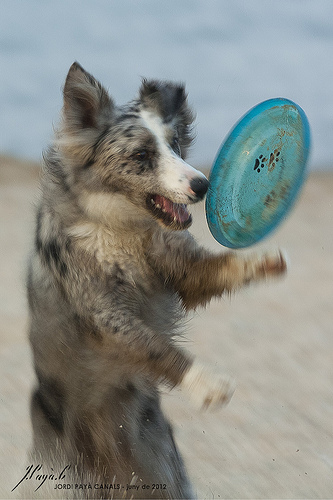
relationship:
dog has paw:
[26, 58, 290, 500] [201, 245, 297, 290]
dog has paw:
[26, 58, 290, 500] [179, 352, 238, 414]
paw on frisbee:
[267, 145, 283, 174] [200, 93, 314, 250]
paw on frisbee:
[252, 151, 268, 180] [200, 93, 314, 250]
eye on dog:
[169, 132, 181, 152] [26, 58, 290, 500]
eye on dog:
[128, 148, 155, 165] [26, 58, 290, 500]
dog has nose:
[26, 58, 290, 500] [149, 148, 212, 198]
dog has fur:
[26, 58, 290, 500] [22, 60, 286, 498]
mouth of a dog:
[142, 186, 199, 227] [26, 58, 290, 500]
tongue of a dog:
[155, 193, 188, 222] [26, 58, 290, 500]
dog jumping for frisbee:
[26, 58, 290, 500] [200, 93, 314, 250]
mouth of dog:
[142, 186, 199, 227] [26, 58, 290, 500]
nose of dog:
[189, 176, 212, 198] [26, 58, 290, 500]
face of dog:
[105, 117, 209, 228] [26, 58, 290, 500]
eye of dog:
[169, 132, 181, 152] [26, 58, 290, 500]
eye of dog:
[128, 148, 155, 165] [26, 58, 290, 500]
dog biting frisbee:
[26, 58, 290, 500] [200, 93, 314, 250]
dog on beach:
[26, 58, 290, 500] [1, 145, 333, 499]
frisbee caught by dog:
[200, 93, 314, 250] [26, 58, 290, 500]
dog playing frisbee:
[26, 58, 290, 500] [200, 93, 314, 250]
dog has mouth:
[26, 58, 290, 500] [142, 186, 199, 227]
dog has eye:
[26, 58, 290, 500] [169, 132, 181, 152]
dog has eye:
[26, 58, 290, 500] [128, 148, 155, 165]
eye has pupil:
[128, 148, 155, 165] [137, 151, 142, 157]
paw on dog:
[201, 245, 297, 290] [26, 58, 290, 500]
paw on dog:
[179, 352, 238, 414] [26, 58, 290, 500]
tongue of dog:
[155, 193, 188, 222] [26, 58, 290, 500]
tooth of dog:
[172, 214, 178, 221] [26, 58, 290, 500]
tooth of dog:
[162, 206, 167, 214] [26, 58, 290, 500]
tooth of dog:
[156, 203, 161, 211] [26, 58, 290, 500]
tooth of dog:
[149, 197, 154, 205] [26, 58, 290, 500]